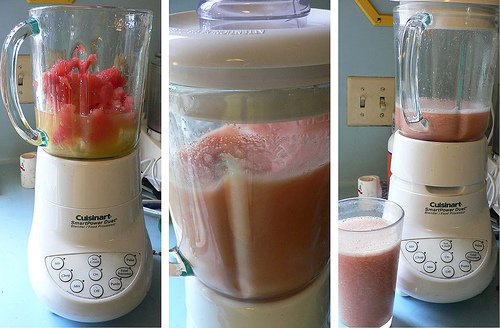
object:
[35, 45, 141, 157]
fruit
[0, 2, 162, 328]
blender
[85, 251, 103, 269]
button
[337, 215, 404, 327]
shake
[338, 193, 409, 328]
glass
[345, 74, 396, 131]
outlet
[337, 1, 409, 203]
wall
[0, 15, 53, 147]
handle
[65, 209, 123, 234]
name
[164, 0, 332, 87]
cover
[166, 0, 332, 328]
blender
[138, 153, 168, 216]
cord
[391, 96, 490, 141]
shake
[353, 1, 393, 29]
frame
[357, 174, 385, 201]
mug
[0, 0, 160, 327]
counter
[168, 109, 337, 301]
groove